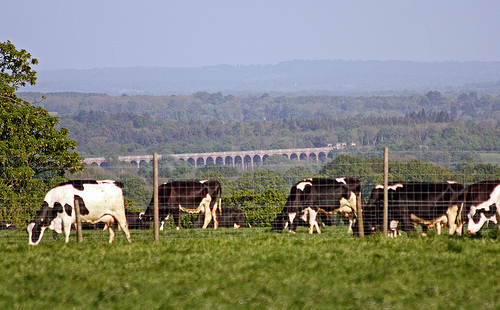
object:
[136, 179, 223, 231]
cow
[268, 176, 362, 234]
cows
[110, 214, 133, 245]
legs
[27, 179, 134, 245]
cow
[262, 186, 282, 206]
trees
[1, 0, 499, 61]
sky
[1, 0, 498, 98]
distance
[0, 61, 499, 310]
land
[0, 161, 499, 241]
fence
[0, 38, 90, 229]
tree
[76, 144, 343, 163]
highway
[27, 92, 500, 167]
distance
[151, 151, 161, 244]
poles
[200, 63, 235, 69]
mountains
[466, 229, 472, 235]
nose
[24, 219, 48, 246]
head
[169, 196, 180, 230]
leg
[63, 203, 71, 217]
spot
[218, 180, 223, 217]
tail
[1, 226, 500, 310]
field